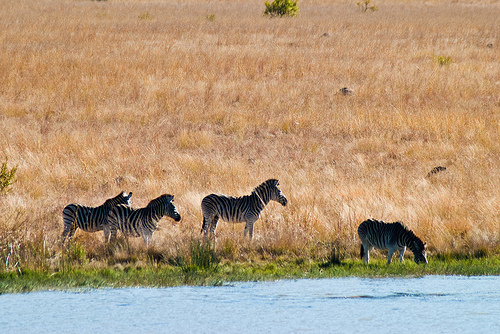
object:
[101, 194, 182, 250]
zebras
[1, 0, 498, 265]
field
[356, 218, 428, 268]
zebra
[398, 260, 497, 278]
grass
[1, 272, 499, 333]
water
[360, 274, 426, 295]
reflection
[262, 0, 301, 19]
tree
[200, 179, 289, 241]
zebra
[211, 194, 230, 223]
stripes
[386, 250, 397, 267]
legs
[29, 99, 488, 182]
grass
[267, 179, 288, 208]
head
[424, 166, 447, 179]
object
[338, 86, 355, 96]
rock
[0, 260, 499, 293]
edge